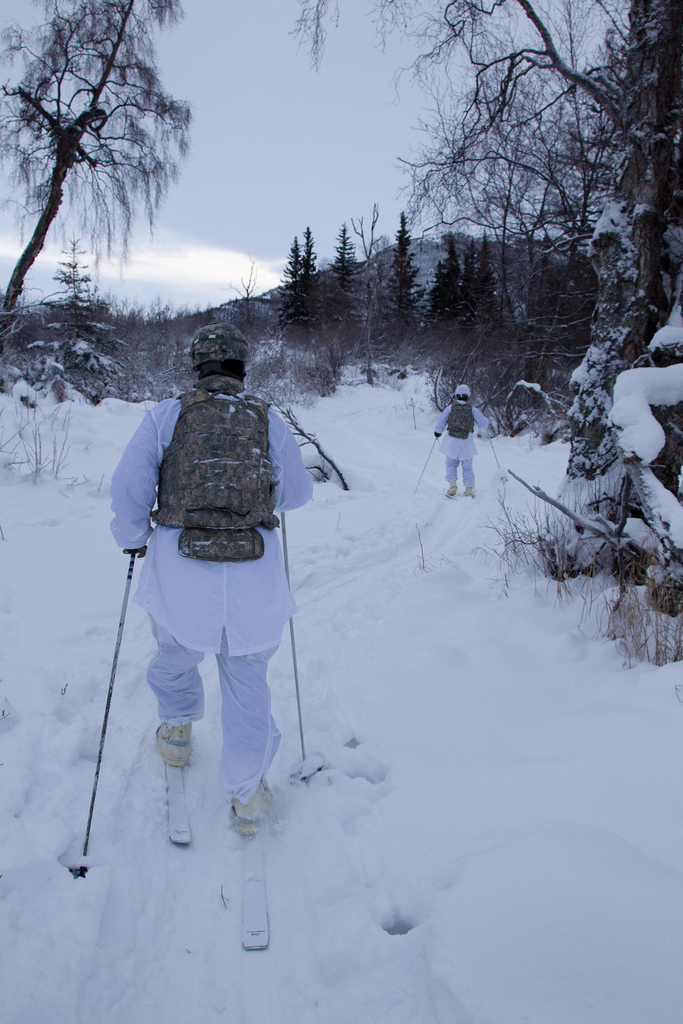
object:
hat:
[188, 323, 251, 373]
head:
[198, 359, 247, 405]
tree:
[276, 227, 323, 333]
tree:
[0, 0, 190, 349]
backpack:
[151, 377, 307, 552]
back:
[122, 365, 377, 604]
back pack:
[125, 381, 302, 550]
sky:
[0, 0, 631, 323]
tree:
[43, 231, 128, 374]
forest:
[276, 201, 499, 326]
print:
[381, 922, 420, 935]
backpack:
[141, 388, 333, 590]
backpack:
[129, 386, 291, 569]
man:
[109, 323, 313, 838]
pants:
[145, 615, 282, 807]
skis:
[167, 764, 267, 949]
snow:
[0, 340, 683, 1024]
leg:
[147, 612, 205, 730]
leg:
[215, 625, 281, 806]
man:
[434, 384, 489, 496]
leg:
[461, 457, 475, 489]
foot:
[156, 721, 193, 767]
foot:
[231, 781, 273, 838]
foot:
[447, 480, 457, 496]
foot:
[464, 487, 475, 499]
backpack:
[152, 373, 282, 564]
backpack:
[446, 394, 475, 438]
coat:
[110, 375, 313, 659]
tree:
[274, 236, 305, 326]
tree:
[386, 211, 427, 329]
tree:
[423, 235, 463, 323]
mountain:
[163, 232, 591, 326]